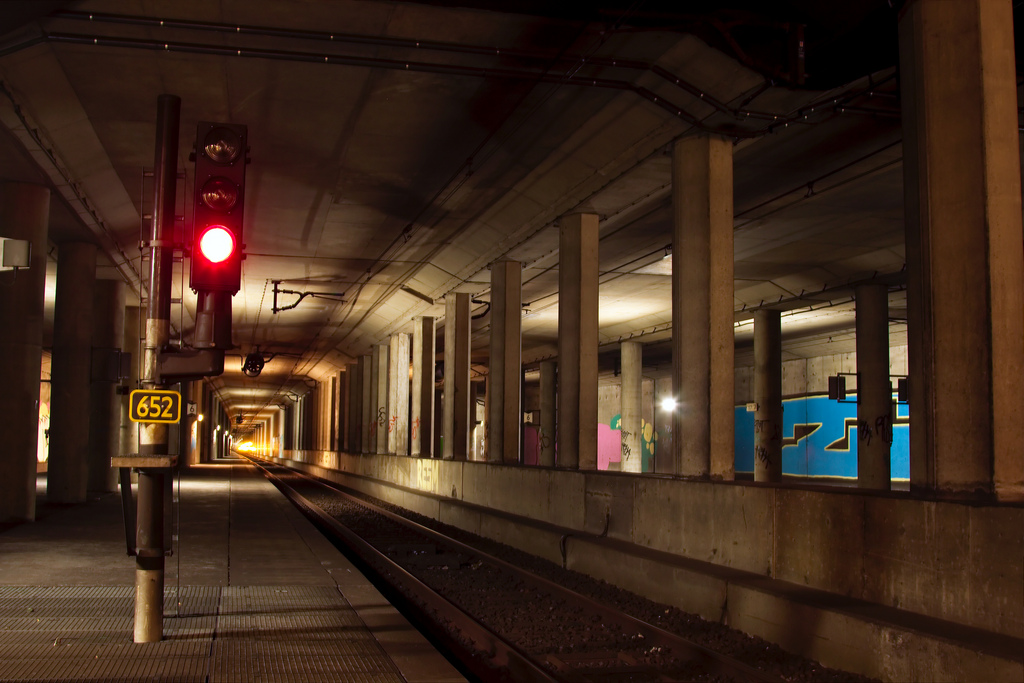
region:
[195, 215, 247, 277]
the light is red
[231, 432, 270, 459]
the light is yellow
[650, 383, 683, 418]
the kight is white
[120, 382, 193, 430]
the numbers are yellow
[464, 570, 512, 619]
the tracks are covered with dirt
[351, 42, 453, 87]
the pipe is black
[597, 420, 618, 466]
the paint is pink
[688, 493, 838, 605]
the barrier is made of concrete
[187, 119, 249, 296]
a red light on a traffic signal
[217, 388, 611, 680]
train tracks in a tunnel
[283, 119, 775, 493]
support columns in a tunnel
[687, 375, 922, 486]
art painted on a cement wall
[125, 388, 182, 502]
a sign on a pole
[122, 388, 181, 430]
a sign with yellow numbers on it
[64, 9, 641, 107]
conduit running across a ceiling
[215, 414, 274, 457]
yellow lights in a tunnel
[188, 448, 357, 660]
a platform next to a train track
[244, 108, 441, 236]
a shadow cast on a cement ceiling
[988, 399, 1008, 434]
pole on the building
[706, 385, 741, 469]
pole on the building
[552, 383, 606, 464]
pole on the building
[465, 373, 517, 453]
pole on the building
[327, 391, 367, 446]
pole on the building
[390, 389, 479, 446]
pole on the building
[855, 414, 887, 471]
pole on the building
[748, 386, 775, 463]
pole on the building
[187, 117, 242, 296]
black metal traffic light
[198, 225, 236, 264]
traffic light lit up red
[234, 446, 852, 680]
double metal subway tracks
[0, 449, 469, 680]
concrete subway platform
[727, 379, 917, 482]
blue, black and white graffiti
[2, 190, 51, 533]
concrete support plinth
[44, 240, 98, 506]
concrete support plinth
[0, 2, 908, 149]
electrical wires is protective coating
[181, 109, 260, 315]
the traffic light is in red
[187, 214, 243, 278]
the light is red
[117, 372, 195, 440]
a sign with number 652 on a pole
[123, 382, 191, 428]
the number is color yellow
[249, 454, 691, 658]
the rail of a train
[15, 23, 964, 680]
rails in a train station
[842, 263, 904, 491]
a column on a train station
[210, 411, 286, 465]
yellow lights on the background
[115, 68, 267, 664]
a traffic light on a pole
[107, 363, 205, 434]
yellow and black sign stating 652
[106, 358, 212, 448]
yellow and black sign stating 652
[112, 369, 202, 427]
yellow and black sign stating 652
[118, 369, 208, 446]
yellow and black sign stating 652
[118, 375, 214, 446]
yellow and black sign stating 652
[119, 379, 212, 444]
yellow and black sign stating 652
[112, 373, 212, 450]
yellow and black sign stating 652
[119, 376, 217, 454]
yellow and black sign stating 652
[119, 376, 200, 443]
yellow and black sign stating 652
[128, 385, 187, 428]
Sign with number 652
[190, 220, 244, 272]
Red traffic light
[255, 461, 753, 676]
Railroad tracks.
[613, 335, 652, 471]
Concrete column with graffiti.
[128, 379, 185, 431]
Black and yellow sign.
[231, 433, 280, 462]
Lights in a tunnel.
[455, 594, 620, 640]
Gravel between train tracks.